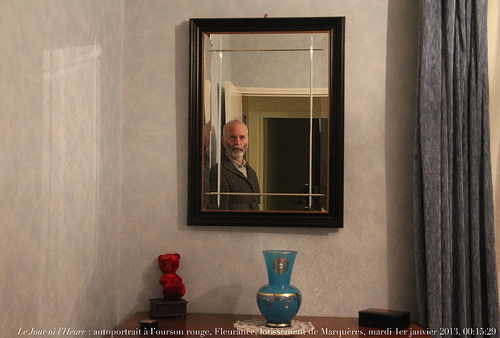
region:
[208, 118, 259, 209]
a man in a miror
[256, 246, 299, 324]
a blue and silver vase on a desk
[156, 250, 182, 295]
a red teddy bear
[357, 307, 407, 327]
a black box on a desk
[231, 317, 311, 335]
a white doily beneath a vase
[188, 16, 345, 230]
a black framed mirror on a wall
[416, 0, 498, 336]
thick blue-gray drapes on a window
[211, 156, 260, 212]
man wearing a jacket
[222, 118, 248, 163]
man with a brown and white beard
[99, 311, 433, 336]
Small brown table against the wall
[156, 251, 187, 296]
Red stuffed animal on the table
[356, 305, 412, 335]
Small black jewelry box on the table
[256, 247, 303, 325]
Light blue vase on the table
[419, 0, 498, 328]
Grey creased curtain bunched to one side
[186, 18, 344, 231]
Black mirror hanging on the wall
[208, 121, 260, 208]
Reflection of a man in the mirror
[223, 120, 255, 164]
Bald man with a white beard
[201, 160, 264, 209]
Man wearing a brown striped jacket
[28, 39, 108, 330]
Glimmer of light on the wall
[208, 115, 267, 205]
a man looking at himself in the mirror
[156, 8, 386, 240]
a mirror on the wall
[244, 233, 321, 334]
a vase on a table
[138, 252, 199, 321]
a red teddy bear on a table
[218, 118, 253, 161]
the head of a man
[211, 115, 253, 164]
a man with a gray beard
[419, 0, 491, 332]
blue curtains beside a mirror on the wall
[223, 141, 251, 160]
the beard of a man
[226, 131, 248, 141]
the eyes of a man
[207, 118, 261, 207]
a man's reflection in the mirror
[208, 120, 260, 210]
a man reflecting in a mirror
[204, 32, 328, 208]
a mirror in a black frame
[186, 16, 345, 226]
a black framed mirror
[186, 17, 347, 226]
a black frame mirror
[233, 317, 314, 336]
a white doily on a wooden stand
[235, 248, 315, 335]
a blue vase on a white doily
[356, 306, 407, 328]
a wooden black box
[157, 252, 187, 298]
a small red teddy bear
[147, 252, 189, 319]
a small teddy bear on a brown box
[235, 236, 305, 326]
vase on the doily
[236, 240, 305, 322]
vase on the doily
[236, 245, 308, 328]
vase on the doily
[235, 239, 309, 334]
vase on the doily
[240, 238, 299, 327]
vase on the doily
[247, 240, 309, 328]
vase on the doily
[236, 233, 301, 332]
vase on the doily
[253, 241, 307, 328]
vase on the doily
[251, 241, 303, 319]
vase on the doily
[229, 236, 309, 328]
blue vase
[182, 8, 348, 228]
mirror with brown wooden frame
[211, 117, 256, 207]
reflection of person in mirror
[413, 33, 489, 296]
gray window covering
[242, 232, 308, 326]
blue vase on wooden table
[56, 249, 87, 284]
white colored wall in room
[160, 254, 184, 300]
the teddy bear is red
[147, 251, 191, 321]
teddy bear is on jewelry box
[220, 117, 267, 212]
man reflection is in mirror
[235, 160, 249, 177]
the shirt is tan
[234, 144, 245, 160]
the beard is gray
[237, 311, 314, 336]
the lace doilie is on chest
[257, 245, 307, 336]
vase is on the doilie